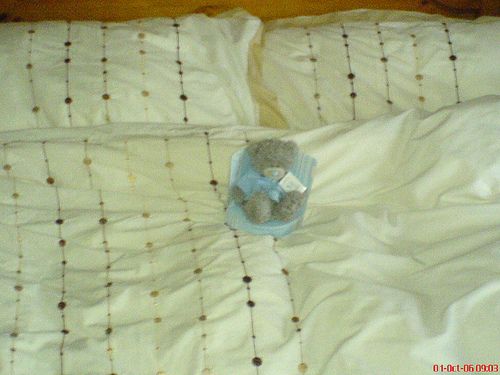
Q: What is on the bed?
A: A teddy bear.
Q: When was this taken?
A: October 1st.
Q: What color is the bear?
A: Gray.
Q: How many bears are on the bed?
A: 1.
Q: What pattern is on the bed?
A: Striped.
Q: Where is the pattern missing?
A: The right side.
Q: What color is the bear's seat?
A: Blue.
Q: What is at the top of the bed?
A: Pillows.